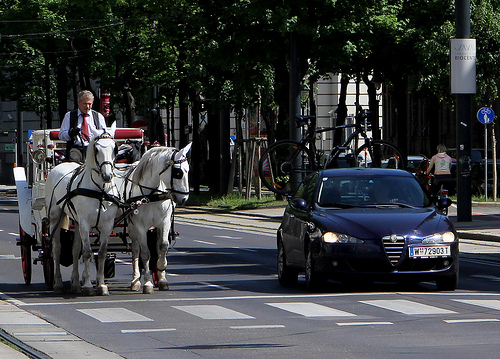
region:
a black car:
[276, 165, 458, 287]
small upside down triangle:
[380, 230, 407, 269]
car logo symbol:
[389, 233, 401, 243]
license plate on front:
[409, 243, 452, 260]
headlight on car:
[422, 229, 454, 244]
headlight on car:
[323, 230, 364, 244]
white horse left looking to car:
[122, 135, 190, 290]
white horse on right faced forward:
[70, 127, 121, 290]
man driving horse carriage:
[64, 86, 104, 156]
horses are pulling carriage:
[26, 123, 63, 162]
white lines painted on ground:
[20, 288, 498, 339]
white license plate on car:
[411, 242, 451, 258]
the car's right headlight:
[322, 229, 338, 242]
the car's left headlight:
[444, 231, 454, 242]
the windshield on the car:
[317, 172, 423, 203]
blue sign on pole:
[477, 102, 496, 125]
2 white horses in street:
[48, 125, 223, 309]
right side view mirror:
[292, 191, 308, 209]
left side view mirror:
[436, 192, 453, 211]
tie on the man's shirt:
[81, 111, 92, 140]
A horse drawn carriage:
[12, 88, 192, 295]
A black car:
[274, 165, 461, 291]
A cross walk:
[1, 293, 498, 335]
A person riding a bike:
[422, 143, 457, 214]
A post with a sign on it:
[451, 2, 477, 222]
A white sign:
[450, 35, 475, 94]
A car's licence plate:
[410, 243, 454, 260]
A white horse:
[45, 118, 117, 293]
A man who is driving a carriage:
[60, 89, 106, 164]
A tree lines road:
[2, 186, 498, 357]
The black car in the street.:
[274, 152, 476, 311]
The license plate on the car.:
[402, 245, 467, 270]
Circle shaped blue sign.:
[477, 102, 499, 132]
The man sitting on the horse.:
[57, 89, 108, 166]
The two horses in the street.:
[38, 134, 183, 304]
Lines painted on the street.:
[77, 293, 489, 344]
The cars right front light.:
[323, 220, 359, 252]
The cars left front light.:
[425, 232, 455, 248]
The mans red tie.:
[77, 118, 89, 147]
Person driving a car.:
[373, 185, 408, 211]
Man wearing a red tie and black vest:
[57, 88, 106, 160]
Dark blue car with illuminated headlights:
[274, 166, 459, 291]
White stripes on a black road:
[0, 217, 499, 334]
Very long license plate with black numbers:
[406, 242, 451, 259]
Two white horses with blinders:
[44, 120, 195, 296]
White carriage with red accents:
[12, 127, 162, 284]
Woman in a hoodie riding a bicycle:
[424, 143, 456, 215]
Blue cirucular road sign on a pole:
[474, 103, 494, 204]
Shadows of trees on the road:
[165, 240, 499, 293]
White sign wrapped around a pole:
[447, 33, 479, 97]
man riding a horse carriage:
[13, 87, 191, 297]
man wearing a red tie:
[59, 89, 109, 161]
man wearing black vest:
[56, 89, 111, 166]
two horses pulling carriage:
[13, 124, 195, 297]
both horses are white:
[40, 120, 193, 295]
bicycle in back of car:
[258, 107, 462, 290]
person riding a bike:
[418, 142, 458, 217]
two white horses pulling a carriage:
[9, 127, 196, 298]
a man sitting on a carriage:
[65, 88, 114, 168]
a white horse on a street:
[52, 120, 120, 298]